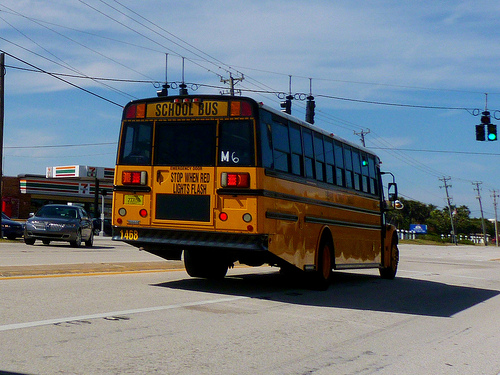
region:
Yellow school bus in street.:
[110, 87, 401, 299]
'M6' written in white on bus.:
[215, 145, 244, 163]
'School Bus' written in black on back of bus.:
[155, 95, 220, 115]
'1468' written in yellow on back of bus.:
[116, 226, 141, 238]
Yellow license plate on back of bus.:
[120, 190, 145, 205]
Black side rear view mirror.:
[385, 180, 395, 205]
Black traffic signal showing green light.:
[485, 120, 498, 143]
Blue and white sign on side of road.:
[406, 220, 422, 230]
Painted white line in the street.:
[0, 285, 275, 331]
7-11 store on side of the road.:
[17, 156, 115, 248]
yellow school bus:
[105, 74, 432, 302]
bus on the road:
[108, 88, 408, 294]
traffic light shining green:
[482, 120, 498, 144]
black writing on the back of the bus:
[166, 166, 214, 197]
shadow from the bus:
[152, 251, 497, 330]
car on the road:
[21, 198, 108, 255]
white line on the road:
[2, 277, 254, 339]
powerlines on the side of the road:
[429, 158, 499, 245]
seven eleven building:
[16, 157, 119, 237]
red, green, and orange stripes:
[49, 164, 83, 179]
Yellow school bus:
[112, 91, 400, 288]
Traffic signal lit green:
[484, 124, 499, 141]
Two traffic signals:
[470, 121, 498, 146]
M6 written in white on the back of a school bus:
[216, 149, 239, 164]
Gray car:
[21, 200, 91, 247]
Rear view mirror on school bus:
[385, 181, 406, 216]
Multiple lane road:
[2, 240, 497, 374]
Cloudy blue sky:
[0, 0, 498, 222]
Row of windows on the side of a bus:
[259, 110, 380, 194]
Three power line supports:
[426, 170, 498, 245]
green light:
[472, 116, 497, 157]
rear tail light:
[215, 165, 245, 195]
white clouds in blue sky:
[18, 9, 86, 79]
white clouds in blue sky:
[15, 72, 59, 119]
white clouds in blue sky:
[42, 58, 92, 145]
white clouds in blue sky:
[61, 24, 116, 65]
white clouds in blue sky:
[121, 22, 185, 57]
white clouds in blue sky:
[193, 16, 254, 61]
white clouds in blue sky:
[281, 16, 398, 73]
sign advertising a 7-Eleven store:
[18, 163, 115, 199]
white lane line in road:
[1, 267, 443, 372]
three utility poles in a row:
[436, 171, 498, 248]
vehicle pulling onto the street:
[20, 201, 97, 250]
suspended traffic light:
[472, 87, 498, 146]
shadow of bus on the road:
[145, 261, 498, 320]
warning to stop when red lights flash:
[168, 169, 212, 196]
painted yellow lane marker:
[0, 265, 260, 281]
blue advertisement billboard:
[408, 221, 430, 233]